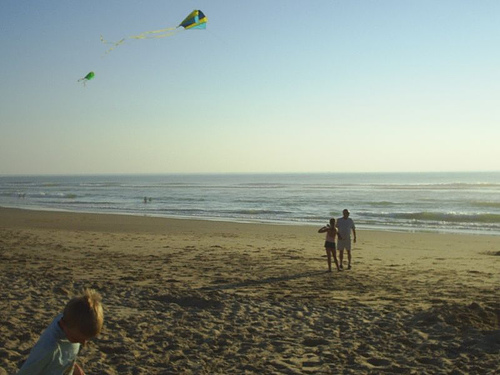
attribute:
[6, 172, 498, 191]
line — horizon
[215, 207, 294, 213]
waves — rolling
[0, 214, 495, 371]
sand — wet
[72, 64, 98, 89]
kite — green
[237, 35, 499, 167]
sky — cloudless, blue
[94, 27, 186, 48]
tail — yellow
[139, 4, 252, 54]
kite — blue, yellow, tourquise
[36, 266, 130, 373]
boy — little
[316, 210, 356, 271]
people — standing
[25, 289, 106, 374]
boy — looking down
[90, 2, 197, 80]
tail — yellow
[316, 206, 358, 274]
people — standing